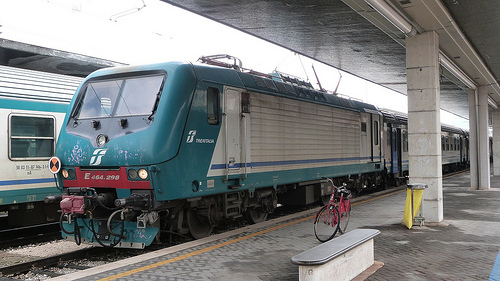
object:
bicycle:
[310, 176, 353, 244]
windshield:
[73, 79, 124, 121]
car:
[49, 54, 394, 253]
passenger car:
[373, 106, 468, 188]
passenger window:
[402, 140, 409, 153]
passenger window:
[444, 143, 449, 152]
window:
[11, 116, 55, 139]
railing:
[0, 244, 106, 277]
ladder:
[217, 192, 246, 221]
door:
[221, 86, 244, 170]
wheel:
[310, 204, 342, 243]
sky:
[0, 0, 493, 137]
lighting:
[362, 0, 417, 38]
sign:
[86, 146, 110, 166]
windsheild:
[110, 75, 165, 117]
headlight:
[57, 169, 69, 179]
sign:
[44, 155, 62, 175]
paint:
[60, 166, 151, 189]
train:
[45, 54, 493, 249]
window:
[113, 73, 167, 119]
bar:
[108, 77, 128, 119]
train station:
[0, 0, 499, 280]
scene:
[0, 0, 499, 280]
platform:
[43, 0, 499, 281]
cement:
[44, 163, 499, 280]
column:
[402, 29, 447, 227]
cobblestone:
[180, 266, 191, 271]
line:
[93, 169, 467, 280]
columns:
[489, 108, 499, 176]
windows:
[71, 75, 124, 120]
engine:
[42, 185, 167, 251]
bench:
[288, 226, 386, 280]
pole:
[406, 188, 416, 220]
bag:
[401, 182, 428, 230]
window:
[11, 138, 54, 159]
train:
[0, 63, 113, 229]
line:
[208, 154, 382, 171]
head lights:
[136, 168, 149, 181]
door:
[370, 111, 385, 165]